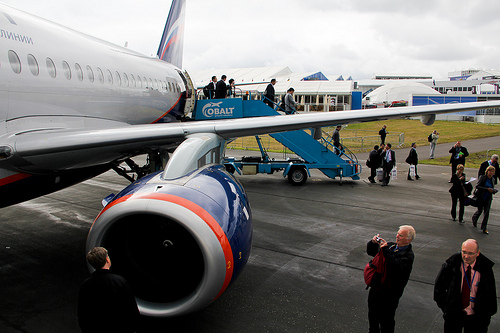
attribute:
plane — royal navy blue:
[4, 10, 497, 292]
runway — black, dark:
[3, 139, 499, 329]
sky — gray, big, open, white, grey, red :
[9, 1, 499, 85]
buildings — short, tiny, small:
[200, 62, 499, 128]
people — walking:
[207, 73, 499, 321]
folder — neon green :
[454, 150, 464, 159]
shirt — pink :
[456, 255, 484, 315]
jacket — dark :
[434, 251, 484, 320]